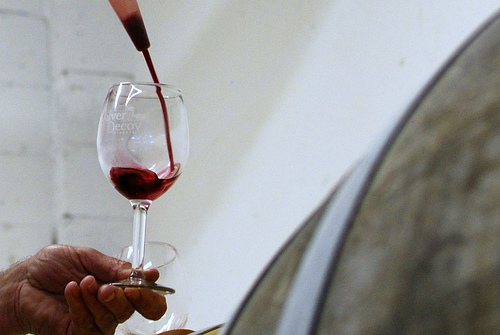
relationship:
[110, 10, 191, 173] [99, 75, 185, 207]
wine into glass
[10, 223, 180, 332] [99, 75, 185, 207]
hand holding glass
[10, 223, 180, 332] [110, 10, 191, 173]
hand pouring wine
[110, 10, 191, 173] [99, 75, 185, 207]
wine with glass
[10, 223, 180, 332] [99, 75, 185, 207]
hand on glass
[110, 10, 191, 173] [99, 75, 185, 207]
wine in glass